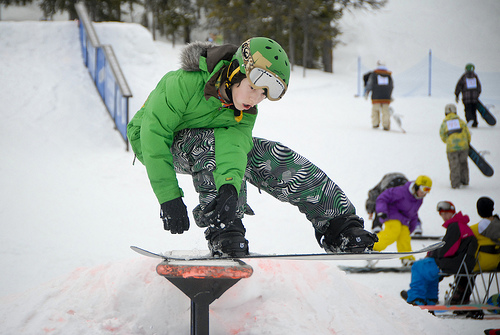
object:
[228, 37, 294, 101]
helmet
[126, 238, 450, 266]
snowboard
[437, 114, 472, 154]
jacket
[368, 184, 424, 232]
jacket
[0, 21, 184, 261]
hill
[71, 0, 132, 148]
ramp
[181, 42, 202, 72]
fur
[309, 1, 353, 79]
trees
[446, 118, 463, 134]
bib number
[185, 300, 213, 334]
post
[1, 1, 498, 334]
snow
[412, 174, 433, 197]
helmet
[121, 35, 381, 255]
snowboarder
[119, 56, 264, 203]
jacket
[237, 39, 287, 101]
goggles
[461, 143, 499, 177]
snowboard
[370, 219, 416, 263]
snowpants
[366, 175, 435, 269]
snowboarder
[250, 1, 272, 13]
leaves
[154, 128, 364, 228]
snowpants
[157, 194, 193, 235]
right black glove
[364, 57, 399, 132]
snowboarder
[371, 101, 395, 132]
snowpants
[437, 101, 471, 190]
snowboarder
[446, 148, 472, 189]
snowpants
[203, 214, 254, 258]
boots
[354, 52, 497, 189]
hill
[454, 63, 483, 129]
snowboarders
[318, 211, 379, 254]
left foot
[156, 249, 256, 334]
rail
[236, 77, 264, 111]
face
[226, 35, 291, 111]
head